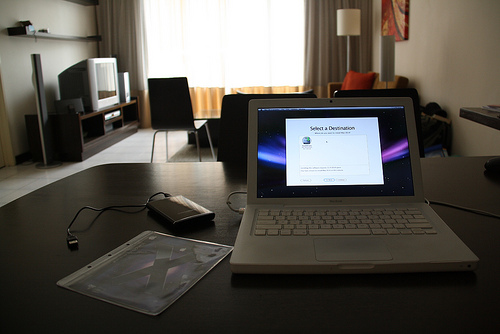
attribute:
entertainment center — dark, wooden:
[27, 49, 144, 166]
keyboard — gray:
[199, 190, 464, 248]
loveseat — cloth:
[330, 87, 420, 98]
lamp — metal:
[336, 10, 362, 80]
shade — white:
[335, 9, 364, 40]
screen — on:
[253, 103, 415, 196]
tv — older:
[59, 54, 119, 114]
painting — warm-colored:
[374, 0, 415, 42]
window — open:
[283, 116, 385, 184]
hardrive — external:
[62, 187, 224, 248]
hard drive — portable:
[150, 191, 217, 232]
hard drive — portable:
[140, 192, 216, 229]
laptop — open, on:
[230, 57, 492, 317]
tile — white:
[7, 172, 37, 189]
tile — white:
[114, 140, 133, 154]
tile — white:
[16, 165, 42, 176]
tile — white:
[106, 147, 125, 157]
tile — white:
[5, 163, 17, 172]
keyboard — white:
[213, 200, 486, 267]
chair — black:
[136, 73, 220, 168]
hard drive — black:
[152, 192, 215, 234]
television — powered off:
[56, 58, 144, 110]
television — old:
[59, 55, 122, 113]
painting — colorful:
[379, 3, 409, 39]